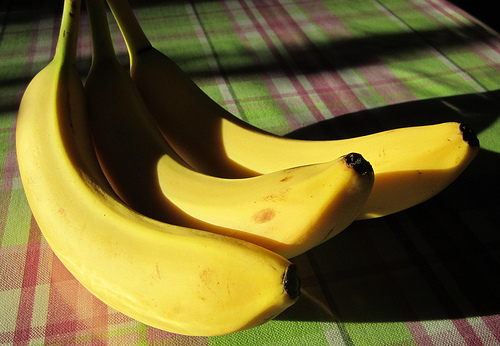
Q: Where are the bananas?
A: On a table.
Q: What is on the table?
A: Bananas.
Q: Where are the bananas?
A: On table.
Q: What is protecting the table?
A: Table cloth.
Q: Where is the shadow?
A: On table.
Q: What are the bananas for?
A: To eat.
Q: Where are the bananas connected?
A: At the stem.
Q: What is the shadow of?
A: Bananas.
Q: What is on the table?
A: Yellow bananas.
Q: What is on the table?
A: Three bananas.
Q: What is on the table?
A: A ripe banana.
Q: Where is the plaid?
A: On the tablecloth.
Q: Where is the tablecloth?
A: On the table.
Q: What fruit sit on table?
A: Bananas.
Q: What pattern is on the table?
A: Stripes.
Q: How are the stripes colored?
A: Red and green.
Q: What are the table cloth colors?
A: Green and purple.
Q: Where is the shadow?
A: Behind the bananas.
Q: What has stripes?
A: Table cloth.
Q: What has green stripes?
A: Table cloths.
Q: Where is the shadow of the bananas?
A: Below the bananas.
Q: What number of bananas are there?
A: 3.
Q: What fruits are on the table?
A: Bananas.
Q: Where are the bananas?
A: On the table.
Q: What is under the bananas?
A: A table.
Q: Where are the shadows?
A: On the table.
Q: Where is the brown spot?
A: On the center banana.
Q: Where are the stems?
A: On the bananas.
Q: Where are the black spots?
A: On the ends of the bananas.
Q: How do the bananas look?
A: Ripe.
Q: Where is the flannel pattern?
A: On the table.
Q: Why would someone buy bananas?
A: To eat them.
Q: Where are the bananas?
A: On the table.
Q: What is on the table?
A: Tablecloth.